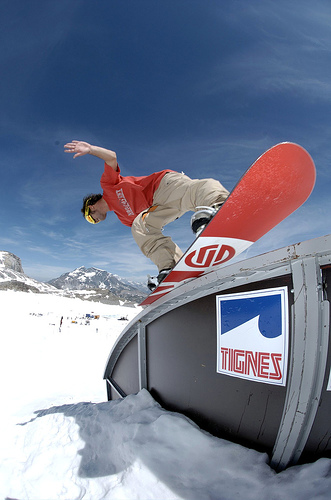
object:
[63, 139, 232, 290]
snowboarder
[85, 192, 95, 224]
goggles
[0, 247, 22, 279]
mountain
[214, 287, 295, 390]
sign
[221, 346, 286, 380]
word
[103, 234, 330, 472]
ramp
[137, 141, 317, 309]
snowboard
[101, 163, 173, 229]
tshirt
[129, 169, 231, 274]
pants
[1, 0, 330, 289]
sky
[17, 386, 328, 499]
shadow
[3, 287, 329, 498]
snow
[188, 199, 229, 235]
snowboot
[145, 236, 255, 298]
design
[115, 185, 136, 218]
writing